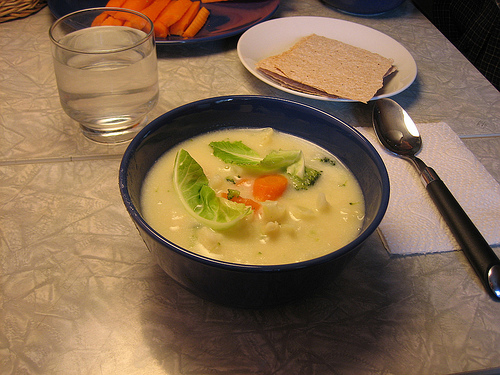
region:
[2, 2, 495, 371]
A table full of food and drink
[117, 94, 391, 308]
A bowl of soup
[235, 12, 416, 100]
A saucer with hard, flat bread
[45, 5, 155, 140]
A clear glass of water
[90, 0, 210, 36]
A pile of cut carrots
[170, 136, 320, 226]
Lettuce slices in soup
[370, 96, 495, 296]
A black handled spoon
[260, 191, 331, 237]
Noodles in soup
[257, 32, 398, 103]
A stack of hard, flat bread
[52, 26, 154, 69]
The surface of water in a glass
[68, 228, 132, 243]
black line on table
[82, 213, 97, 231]
black line on table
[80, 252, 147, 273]
black line on table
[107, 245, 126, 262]
black line on table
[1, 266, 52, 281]
black line on table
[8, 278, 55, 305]
black line on table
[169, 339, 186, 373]
black line on table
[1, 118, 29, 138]
black line on table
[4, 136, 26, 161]
black line on table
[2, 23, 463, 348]
this is a dinner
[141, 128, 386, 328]
this is an appetizer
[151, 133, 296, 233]
the soup has vegetables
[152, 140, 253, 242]
there is lettuce in the soup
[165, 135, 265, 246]
the lettuce is light green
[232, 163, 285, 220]
the carrots are orange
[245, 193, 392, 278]
these are potatoes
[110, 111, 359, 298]
soup in the plate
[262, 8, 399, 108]
bread in the bowl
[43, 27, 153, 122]
water in the cup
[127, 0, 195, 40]
carrots on the plate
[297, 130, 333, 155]
the bowl is blue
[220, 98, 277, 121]
the bowl is glass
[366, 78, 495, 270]
spoon on the napkin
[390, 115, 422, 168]
the spoon is silver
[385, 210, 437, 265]
the napkin is white